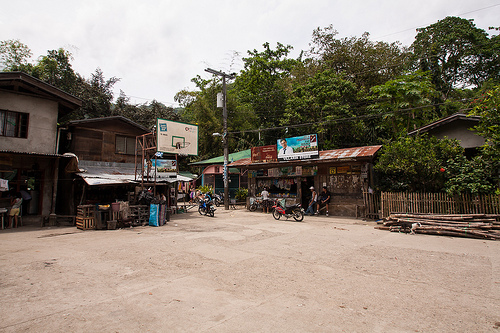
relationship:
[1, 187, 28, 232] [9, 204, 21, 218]
person wearing shorts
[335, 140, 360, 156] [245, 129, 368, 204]
metal roof on building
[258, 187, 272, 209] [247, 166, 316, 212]
man buys at outdoor market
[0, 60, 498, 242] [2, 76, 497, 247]
buildings have stalls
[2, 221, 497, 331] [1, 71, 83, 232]
field by building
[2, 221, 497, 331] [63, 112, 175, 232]
field by building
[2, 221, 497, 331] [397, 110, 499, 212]
field by building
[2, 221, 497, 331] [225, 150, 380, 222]
field by building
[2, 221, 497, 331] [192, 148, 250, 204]
field by building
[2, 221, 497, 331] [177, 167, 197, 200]
field by building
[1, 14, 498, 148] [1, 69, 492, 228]
trees behind buildings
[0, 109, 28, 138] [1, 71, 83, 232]
window on building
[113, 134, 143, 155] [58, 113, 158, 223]
window on building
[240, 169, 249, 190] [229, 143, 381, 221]
window on building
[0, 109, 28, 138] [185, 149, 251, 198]
window on building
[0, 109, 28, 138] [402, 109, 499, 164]
window on building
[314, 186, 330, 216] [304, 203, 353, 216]
guy on bench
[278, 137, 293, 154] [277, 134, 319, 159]
person on billboard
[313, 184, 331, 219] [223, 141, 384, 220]
guy in front of store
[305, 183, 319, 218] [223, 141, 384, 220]
guy in front of store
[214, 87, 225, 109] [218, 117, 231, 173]
light fixture mounted on utility pole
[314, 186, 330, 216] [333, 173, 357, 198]
guy sitting on wall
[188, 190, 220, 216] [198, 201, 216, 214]
man riding bicycle